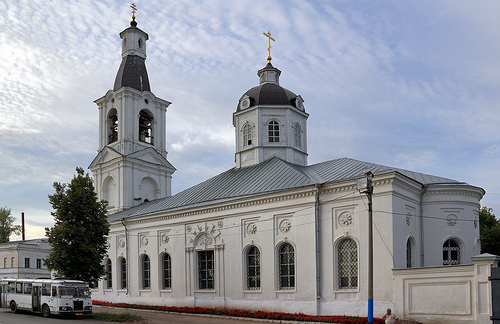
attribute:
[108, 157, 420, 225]
church — white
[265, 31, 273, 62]
cross — gold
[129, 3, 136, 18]
cross — gold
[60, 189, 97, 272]
tree — green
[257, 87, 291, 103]
roof — black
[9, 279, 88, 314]
bus — white